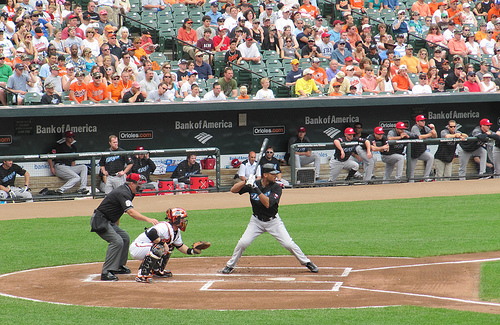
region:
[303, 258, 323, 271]
left foot on man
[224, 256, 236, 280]
the player's right foot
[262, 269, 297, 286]
home plate on field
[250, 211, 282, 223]
black belt on the player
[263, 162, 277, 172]
black helmet on head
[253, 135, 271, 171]
baseball bat in hand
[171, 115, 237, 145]
bank of america logo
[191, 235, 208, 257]
glove on catcher's hand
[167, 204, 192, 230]
the catcher's mask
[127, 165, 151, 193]
mask on the umpire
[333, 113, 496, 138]
a row of red ball caps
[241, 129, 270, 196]
a metal baseball bat in the players hand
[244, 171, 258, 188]
the white gloves on the players hand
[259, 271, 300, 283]
a white home plate in the dirt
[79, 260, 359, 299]
the lines made of chalk in the dirt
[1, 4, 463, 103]
a large crowd in the stands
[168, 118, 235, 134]
white letters in the dugout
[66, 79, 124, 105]
a row of people with orange shirts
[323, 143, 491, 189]
a row of men with gray pants on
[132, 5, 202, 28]
a row of empty seats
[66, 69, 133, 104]
Four people in orange shirts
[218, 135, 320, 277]
Baseball player holding baseball bat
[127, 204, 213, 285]
Catcher holding baseball mit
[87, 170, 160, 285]
Man in baseball umpire uniform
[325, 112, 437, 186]
Four men in red baseball caps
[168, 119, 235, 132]
Bank of America sign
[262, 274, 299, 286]
Baseball home plate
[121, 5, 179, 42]
Empty green seats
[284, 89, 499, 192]
Baseball players waiting in dugout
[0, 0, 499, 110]
Spectators watching a game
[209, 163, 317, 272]
batter in the field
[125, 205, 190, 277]
catcher on the field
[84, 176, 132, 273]
umpire in the field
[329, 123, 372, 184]
player in the dugout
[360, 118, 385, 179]
player in the dugout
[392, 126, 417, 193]
player in the dugoput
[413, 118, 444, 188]
player in the dugout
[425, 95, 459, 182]
player in the dugout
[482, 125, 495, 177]
player in the dugout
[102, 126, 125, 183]
player in the dugout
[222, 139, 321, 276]
Baseball player in batting stance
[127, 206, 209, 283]
Catcher in front of the umpire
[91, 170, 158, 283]
Umpire with hand on catcher's back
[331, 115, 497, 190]
Players standing along dugout fence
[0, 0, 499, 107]
People in the stands watching the game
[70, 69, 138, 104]
Four men wearing orange s hirts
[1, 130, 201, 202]
Players sitting in dugout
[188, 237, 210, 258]
Baseball mitt on catcher's left hand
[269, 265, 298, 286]
Base at home plate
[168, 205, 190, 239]
Protective mask on catcher's face